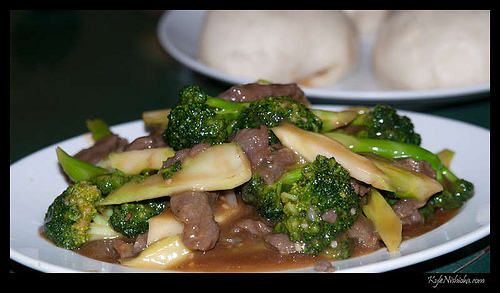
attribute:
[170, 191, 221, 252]
beef — brown, sauteed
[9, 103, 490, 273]
plate — white, ceramic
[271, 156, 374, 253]
broccoli — green, chopped, cut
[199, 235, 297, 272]
sauce — brown, soup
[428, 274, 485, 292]
graphic — white, photographer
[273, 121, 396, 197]
bamboo shoot — beige, cut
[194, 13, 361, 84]
dough ball — white, folded, dumpling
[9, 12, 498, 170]
table — black